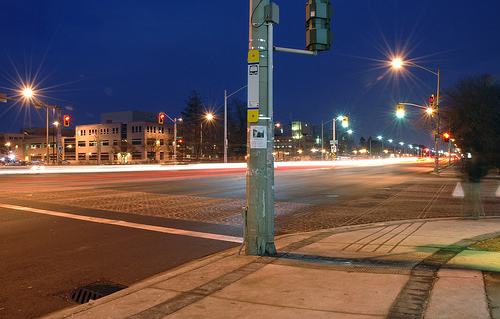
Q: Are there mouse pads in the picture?
A: No, there are no mouse pads.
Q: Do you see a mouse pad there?
A: No, there are no mouse pads.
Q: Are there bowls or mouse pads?
A: No, there are no mouse pads or bowls.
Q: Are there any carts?
A: No, there are no carts.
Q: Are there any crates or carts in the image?
A: No, there are no carts or crates.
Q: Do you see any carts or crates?
A: No, there are no carts or crates.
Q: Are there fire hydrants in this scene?
A: No, there are no fire hydrants.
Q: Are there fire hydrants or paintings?
A: No, there are no fire hydrants or paintings.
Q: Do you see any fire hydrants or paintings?
A: No, there are no fire hydrants or paintings.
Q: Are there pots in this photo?
A: No, there are no pots.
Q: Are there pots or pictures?
A: No, there are no pots or pictures.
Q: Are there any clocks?
A: No, there are no clocks.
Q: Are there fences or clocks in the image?
A: No, there are no clocks or fences.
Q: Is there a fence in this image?
A: No, there are no fences.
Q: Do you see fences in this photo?
A: No, there are no fences.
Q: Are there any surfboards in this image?
A: No, there are no surfboards.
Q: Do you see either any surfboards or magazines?
A: No, there are no surfboards or magazines.